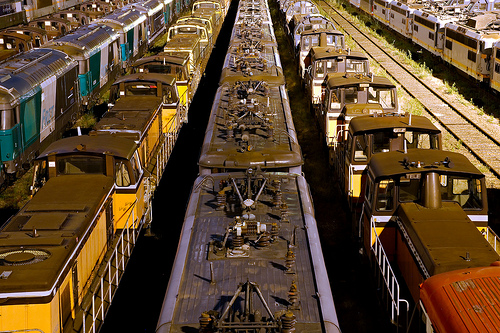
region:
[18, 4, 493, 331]
a train yard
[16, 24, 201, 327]
a row of yellow train cars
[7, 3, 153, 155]
a row of blue train cars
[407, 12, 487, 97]
a row of white and yellow train cars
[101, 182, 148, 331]
a metal ladder on the side of a car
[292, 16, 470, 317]
orange yellow vehicle with ladder on side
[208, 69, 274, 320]
rusty mechanisms on top of train car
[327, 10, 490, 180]
empty train tracks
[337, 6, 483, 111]
green grass growing along the train tracks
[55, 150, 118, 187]
train window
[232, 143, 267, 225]
top of a rail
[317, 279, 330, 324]
edge of a rail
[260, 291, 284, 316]
part of a metal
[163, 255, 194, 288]
part of the train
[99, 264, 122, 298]
part of a balcony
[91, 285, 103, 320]
part of a post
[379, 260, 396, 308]
part of a fence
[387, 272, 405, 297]
part of a metal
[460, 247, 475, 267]
part of a bolt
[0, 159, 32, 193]
part of the ground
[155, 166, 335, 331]
the part of a train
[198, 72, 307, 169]
the part of a train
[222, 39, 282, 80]
the part of a train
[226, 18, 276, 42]
the part of a train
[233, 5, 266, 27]
the part of a train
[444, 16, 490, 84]
the part of a train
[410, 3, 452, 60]
the part of a train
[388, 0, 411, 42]
the part of a train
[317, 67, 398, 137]
the part of a train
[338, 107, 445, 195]
the part of a train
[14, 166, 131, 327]
the part of a train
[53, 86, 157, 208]
the part of a train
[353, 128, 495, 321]
the part of a train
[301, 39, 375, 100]
the part of a train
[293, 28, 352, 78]
the part of a train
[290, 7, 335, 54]
the part of a train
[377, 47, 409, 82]
Train tracks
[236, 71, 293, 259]
Metal top of a train.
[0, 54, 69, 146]
A silver,green and white train car.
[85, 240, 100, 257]
Side of a train car is yellow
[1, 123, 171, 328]
Train engine.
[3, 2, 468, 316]
A yard full of trains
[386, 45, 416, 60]
Vegetation beside the railroad track.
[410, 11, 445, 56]
A silver train car with yellow stripes.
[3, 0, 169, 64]
A group of trains connected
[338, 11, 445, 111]
Sun is shining on the train track.